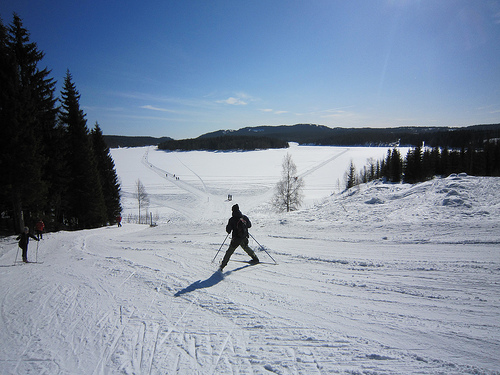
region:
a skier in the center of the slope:
[212, 200, 281, 292]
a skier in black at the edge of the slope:
[15, 215, 55, 277]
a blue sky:
[59, 12, 476, 123]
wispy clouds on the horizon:
[102, 87, 464, 121]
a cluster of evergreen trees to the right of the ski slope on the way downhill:
[0, 80, 120, 223]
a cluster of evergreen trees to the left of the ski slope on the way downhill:
[331, 145, 494, 190]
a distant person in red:
[32, 219, 54, 243]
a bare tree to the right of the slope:
[273, 154, 309, 215]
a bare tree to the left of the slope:
[125, 172, 166, 235]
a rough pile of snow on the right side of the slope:
[330, 182, 495, 217]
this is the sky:
[161, 5, 443, 97]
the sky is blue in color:
[181, 0, 268, 55]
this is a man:
[223, 202, 256, 266]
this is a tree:
[60, 73, 104, 197]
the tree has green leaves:
[61, 90, 71, 96]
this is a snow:
[56, 271, 123, 335]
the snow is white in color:
[36, 307, 113, 342]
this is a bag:
[236, 218, 246, 238]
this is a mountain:
[261, 124, 329, 135]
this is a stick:
[36, 240, 38, 265]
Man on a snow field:
[197, 187, 278, 273]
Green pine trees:
[2, 13, 138, 233]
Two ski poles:
[207, 226, 282, 264]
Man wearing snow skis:
[197, 197, 278, 277]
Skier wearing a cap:
[202, 195, 279, 275]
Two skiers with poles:
[6, 200, 291, 282]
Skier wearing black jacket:
[205, 197, 284, 272]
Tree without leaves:
[266, 149, 313, 220]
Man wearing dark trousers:
[199, 197, 289, 272]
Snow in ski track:
[308, 180, 498, 347]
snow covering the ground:
[57, 302, 348, 347]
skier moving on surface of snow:
[206, 200, 276, 270]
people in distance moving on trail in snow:
[145, 157, 190, 183]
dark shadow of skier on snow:
[165, 261, 250, 301]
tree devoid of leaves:
[270, 146, 305, 216]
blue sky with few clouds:
[85, 5, 490, 125]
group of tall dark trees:
[0, 5, 120, 217]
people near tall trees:
[6, 10, 51, 265]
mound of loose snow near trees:
[331, 145, 497, 225]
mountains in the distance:
[186, 120, 367, 137]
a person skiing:
[209, 201, 279, 276]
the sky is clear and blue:
[0, 1, 497, 141]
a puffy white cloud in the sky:
[206, 85, 254, 107]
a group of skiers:
[162, 169, 183, 184]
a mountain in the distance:
[200, 122, 334, 141]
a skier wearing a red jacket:
[34, 218, 44, 232]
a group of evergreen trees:
[0, 7, 126, 240]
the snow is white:
[1, 140, 498, 374]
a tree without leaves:
[269, 151, 308, 216]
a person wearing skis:
[218, 254, 280, 277]